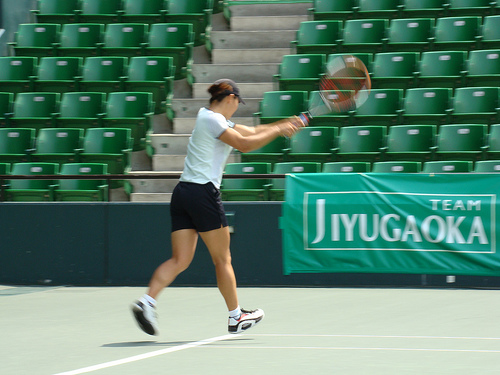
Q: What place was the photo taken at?
A: It was taken at the stadium.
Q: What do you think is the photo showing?
A: It is showing a stadium.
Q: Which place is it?
A: It is a stadium.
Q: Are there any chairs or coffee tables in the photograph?
A: Yes, there is a chair.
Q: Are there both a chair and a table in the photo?
A: No, there is a chair but no tables.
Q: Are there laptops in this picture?
A: No, there are no laptops.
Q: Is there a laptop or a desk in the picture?
A: No, there are no laptops or desks.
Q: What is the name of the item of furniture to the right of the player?
A: The piece of furniture is a chair.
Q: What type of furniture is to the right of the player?
A: The piece of furniture is a chair.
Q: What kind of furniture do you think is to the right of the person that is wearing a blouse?
A: The piece of furniture is a chair.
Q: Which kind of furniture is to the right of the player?
A: The piece of furniture is a chair.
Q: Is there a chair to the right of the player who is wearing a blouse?
A: Yes, there is a chair to the right of the player.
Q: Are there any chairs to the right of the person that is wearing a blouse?
A: Yes, there is a chair to the right of the player.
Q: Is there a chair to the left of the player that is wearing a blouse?
A: No, the chair is to the right of the player.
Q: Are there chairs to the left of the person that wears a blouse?
A: No, the chair is to the right of the player.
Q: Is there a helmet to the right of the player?
A: No, there is a chair to the right of the player.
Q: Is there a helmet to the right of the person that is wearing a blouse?
A: No, there is a chair to the right of the player.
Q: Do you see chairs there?
A: Yes, there is a chair.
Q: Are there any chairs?
A: Yes, there is a chair.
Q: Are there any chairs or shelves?
A: Yes, there is a chair.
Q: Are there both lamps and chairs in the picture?
A: No, there is a chair but no lamps.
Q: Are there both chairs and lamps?
A: No, there is a chair but no lamps.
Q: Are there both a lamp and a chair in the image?
A: No, there is a chair but no lamps.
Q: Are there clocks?
A: No, there are no clocks.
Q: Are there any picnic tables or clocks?
A: No, there are no clocks or picnic tables.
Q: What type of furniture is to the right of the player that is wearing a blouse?
A: The piece of furniture is a chair.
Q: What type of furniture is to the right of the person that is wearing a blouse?
A: The piece of furniture is a chair.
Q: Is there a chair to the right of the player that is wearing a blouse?
A: Yes, there is a chair to the right of the player.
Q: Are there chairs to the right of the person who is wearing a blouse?
A: Yes, there is a chair to the right of the player.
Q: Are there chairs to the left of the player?
A: No, the chair is to the right of the player.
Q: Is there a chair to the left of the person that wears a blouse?
A: No, the chair is to the right of the player.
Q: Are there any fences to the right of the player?
A: No, there is a chair to the right of the player.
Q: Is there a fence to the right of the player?
A: No, there is a chair to the right of the player.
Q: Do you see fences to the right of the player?
A: No, there is a chair to the right of the player.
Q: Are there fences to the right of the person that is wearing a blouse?
A: No, there is a chair to the right of the player.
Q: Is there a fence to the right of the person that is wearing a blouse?
A: No, there is a chair to the right of the player.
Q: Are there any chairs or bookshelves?
A: Yes, there is a chair.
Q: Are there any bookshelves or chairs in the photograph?
A: Yes, there is a chair.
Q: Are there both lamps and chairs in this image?
A: No, there is a chair but no lamps.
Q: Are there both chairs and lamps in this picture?
A: No, there is a chair but no lamps.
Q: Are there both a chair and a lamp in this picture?
A: No, there is a chair but no lamps.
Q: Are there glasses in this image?
A: No, there are no glasses.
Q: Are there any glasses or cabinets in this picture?
A: No, there are no glasses or cabinets.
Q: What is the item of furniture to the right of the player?
A: The piece of furniture is a chair.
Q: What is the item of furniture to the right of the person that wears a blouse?
A: The piece of furniture is a chair.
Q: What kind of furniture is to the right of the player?
A: The piece of furniture is a chair.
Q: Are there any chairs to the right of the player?
A: Yes, there is a chair to the right of the player.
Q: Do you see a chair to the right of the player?
A: Yes, there is a chair to the right of the player.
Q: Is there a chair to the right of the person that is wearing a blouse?
A: Yes, there is a chair to the right of the player.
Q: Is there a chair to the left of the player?
A: No, the chair is to the right of the player.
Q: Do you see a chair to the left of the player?
A: No, the chair is to the right of the player.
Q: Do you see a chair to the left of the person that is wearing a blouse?
A: No, the chair is to the right of the player.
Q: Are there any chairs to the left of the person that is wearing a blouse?
A: No, the chair is to the right of the player.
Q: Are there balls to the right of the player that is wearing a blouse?
A: No, there is a chair to the right of the player.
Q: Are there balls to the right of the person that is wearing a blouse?
A: No, there is a chair to the right of the player.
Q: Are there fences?
A: No, there are no fences.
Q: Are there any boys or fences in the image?
A: No, there are no fences or boys.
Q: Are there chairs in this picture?
A: Yes, there is a chair.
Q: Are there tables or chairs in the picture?
A: Yes, there is a chair.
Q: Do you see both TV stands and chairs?
A: No, there is a chair but no TV stands.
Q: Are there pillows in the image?
A: No, there are no pillows.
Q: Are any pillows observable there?
A: No, there are no pillows.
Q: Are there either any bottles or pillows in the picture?
A: No, there are no pillows or bottles.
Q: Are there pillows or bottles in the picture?
A: No, there are no pillows or bottles.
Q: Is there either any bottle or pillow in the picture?
A: No, there are no pillows or bottles.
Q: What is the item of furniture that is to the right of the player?
A: The piece of furniture is a chair.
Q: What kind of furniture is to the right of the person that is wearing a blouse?
A: The piece of furniture is a chair.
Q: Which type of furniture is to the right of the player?
A: The piece of furniture is a chair.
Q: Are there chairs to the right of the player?
A: Yes, there is a chair to the right of the player.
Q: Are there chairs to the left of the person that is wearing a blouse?
A: No, the chair is to the right of the player.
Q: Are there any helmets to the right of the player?
A: No, there is a chair to the right of the player.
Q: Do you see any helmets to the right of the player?
A: No, there is a chair to the right of the player.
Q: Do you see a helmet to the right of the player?
A: No, there is a chair to the right of the player.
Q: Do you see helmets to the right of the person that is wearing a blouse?
A: No, there is a chair to the right of the player.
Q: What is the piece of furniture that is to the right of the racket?
A: The piece of furniture is a chair.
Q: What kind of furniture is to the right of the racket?
A: The piece of furniture is a chair.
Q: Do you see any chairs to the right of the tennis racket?
A: Yes, there is a chair to the right of the tennis racket.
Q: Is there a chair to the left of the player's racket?
A: No, the chair is to the right of the tennis racket.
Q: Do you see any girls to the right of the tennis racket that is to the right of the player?
A: No, there is a chair to the right of the tennis racket.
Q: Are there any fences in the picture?
A: No, there are no fences.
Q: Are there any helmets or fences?
A: No, there are no fences or helmets.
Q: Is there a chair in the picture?
A: Yes, there is a chair.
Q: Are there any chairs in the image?
A: Yes, there is a chair.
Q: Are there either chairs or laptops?
A: Yes, there is a chair.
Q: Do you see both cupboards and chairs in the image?
A: No, there is a chair but no cupboards.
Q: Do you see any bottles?
A: No, there are no bottles.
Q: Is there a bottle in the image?
A: No, there are no bottles.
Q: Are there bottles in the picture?
A: No, there are no bottles.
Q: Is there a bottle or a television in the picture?
A: No, there are no bottles or televisions.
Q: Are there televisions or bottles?
A: No, there are no bottles or televisions.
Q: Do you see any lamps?
A: No, there are no lamps.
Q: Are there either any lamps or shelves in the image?
A: No, there are no lamps or shelves.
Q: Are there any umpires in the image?
A: No, there are no umpires.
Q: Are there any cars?
A: No, there are no cars.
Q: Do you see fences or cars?
A: No, there are no cars or fences.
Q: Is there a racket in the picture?
A: Yes, there is a racket.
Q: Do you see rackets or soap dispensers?
A: Yes, there is a racket.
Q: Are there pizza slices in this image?
A: No, there are no pizza slices.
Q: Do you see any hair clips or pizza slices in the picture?
A: No, there are no pizza slices or hair clips.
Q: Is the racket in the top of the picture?
A: Yes, the racket is in the top of the image.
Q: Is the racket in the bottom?
A: No, the racket is in the top of the image.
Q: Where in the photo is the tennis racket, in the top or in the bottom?
A: The tennis racket is in the top of the image.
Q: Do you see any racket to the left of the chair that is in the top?
A: Yes, there is a racket to the left of the chair.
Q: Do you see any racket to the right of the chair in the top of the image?
A: No, the racket is to the left of the chair.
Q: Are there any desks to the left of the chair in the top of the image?
A: No, there is a racket to the left of the chair.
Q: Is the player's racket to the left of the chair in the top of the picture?
A: Yes, the tennis racket is to the left of the chair.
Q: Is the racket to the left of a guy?
A: No, the racket is to the left of the chair.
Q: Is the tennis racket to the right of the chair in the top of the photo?
A: No, the tennis racket is to the left of the chair.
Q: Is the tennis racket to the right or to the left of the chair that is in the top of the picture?
A: The tennis racket is to the left of the chair.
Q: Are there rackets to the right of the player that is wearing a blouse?
A: Yes, there is a racket to the right of the player.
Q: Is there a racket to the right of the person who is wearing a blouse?
A: Yes, there is a racket to the right of the player.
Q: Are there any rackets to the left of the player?
A: No, the racket is to the right of the player.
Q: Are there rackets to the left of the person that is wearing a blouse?
A: No, the racket is to the right of the player.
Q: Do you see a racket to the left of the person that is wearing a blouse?
A: No, the racket is to the right of the player.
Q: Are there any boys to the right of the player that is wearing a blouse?
A: No, there is a racket to the right of the player.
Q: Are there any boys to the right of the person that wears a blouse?
A: No, there is a racket to the right of the player.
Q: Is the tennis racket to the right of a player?
A: Yes, the tennis racket is to the right of a player.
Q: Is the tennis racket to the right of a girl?
A: No, the tennis racket is to the right of a player.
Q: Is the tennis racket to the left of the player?
A: No, the tennis racket is to the right of the player.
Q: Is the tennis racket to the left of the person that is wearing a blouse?
A: No, the tennis racket is to the right of the player.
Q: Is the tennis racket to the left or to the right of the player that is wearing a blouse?
A: The tennis racket is to the right of the player.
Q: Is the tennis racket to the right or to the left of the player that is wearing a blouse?
A: The tennis racket is to the right of the player.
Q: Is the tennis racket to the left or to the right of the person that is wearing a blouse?
A: The tennis racket is to the right of the player.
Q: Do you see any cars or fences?
A: No, there are no cars or fences.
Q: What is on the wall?
A: The sign is on the wall.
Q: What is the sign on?
A: The sign is on the wall.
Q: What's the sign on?
A: The sign is on the wall.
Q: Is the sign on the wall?
A: Yes, the sign is on the wall.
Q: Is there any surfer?
A: No, there are no surfers.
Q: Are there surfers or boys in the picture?
A: No, there are no surfers or boys.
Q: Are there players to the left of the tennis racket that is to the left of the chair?
A: Yes, there is a player to the left of the tennis racket.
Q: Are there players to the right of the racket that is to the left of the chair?
A: No, the player is to the left of the racket.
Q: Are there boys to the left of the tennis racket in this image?
A: No, there is a player to the left of the tennis racket.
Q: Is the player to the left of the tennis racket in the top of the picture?
A: Yes, the player is to the left of the racket.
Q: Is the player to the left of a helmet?
A: No, the player is to the left of the racket.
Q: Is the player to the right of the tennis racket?
A: No, the player is to the left of the tennis racket.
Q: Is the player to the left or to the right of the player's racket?
A: The player is to the left of the racket.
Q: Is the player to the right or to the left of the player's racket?
A: The player is to the left of the racket.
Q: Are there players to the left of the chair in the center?
A: Yes, there is a player to the left of the chair.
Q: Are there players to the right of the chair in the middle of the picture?
A: No, the player is to the left of the chair.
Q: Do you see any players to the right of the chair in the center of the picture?
A: No, the player is to the left of the chair.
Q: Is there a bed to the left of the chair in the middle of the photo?
A: No, there is a player to the left of the chair.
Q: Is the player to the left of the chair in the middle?
A: Yes, the player is to the left of the chair.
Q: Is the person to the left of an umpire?
A: No, the player is to the left of the chair.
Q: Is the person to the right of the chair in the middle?
A: No, the player is to the left of the chair.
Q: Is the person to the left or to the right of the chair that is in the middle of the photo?
A: The player is to the left of the chair.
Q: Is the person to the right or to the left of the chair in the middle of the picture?
A: The player is to the left of the chair.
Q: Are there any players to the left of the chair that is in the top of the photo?
A: Yes, there is a player to the left of the chair.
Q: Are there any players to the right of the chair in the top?
A: No, the player is to the left of the chair.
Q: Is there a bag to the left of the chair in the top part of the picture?
A: No, there is a player to the left of the chair.